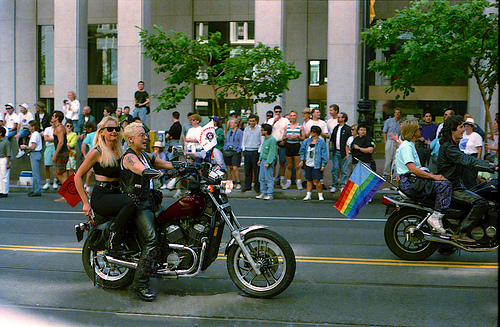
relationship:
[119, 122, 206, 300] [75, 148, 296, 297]
person on motorcycle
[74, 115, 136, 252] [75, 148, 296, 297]
person on motorcycle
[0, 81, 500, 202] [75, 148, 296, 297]
spectators behind motorcycle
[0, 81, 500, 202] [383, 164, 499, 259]
spectators behind motorcycle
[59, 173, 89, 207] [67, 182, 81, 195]
flag has circle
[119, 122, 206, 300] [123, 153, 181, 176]
person has arm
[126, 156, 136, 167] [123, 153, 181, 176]
tattoo on arm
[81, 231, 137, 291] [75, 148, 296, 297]
tire on motorcycle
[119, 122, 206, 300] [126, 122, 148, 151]
person has head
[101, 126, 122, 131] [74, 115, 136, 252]
sunglasses on person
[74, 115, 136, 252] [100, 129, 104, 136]
person has ear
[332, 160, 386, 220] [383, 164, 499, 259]
flag on motorcycle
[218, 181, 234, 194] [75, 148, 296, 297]
headlight on motorcycle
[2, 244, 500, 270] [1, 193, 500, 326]
line in road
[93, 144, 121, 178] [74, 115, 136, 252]
crop top on person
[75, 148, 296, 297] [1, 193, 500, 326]
motorcycle on road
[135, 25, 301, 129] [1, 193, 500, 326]
tree by road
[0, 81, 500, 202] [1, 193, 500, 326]
spectators on side of road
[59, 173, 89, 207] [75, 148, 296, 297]
flag on motorcycle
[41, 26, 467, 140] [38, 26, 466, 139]
reflection on glass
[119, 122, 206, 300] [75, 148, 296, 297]
person riding motorcycle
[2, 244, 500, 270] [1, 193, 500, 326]
line on road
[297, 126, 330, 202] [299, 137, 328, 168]
person wearing jacket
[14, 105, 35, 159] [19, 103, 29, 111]
person wearing hat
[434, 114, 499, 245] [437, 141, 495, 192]
man wearing jacket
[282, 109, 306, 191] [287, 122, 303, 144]
person wearing shirt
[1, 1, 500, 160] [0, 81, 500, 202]
building behind spectators